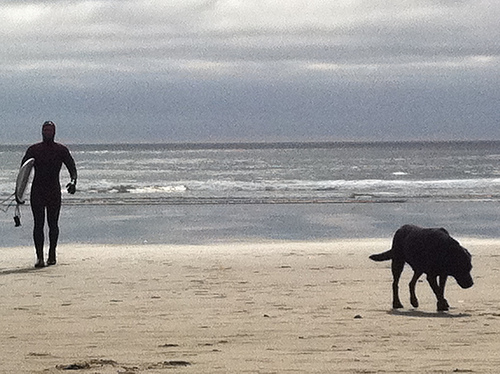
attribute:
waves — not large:
[3, 143, 494, 204]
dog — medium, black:
[369, 226, 481, 316]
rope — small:
[0, 191, 22, 228]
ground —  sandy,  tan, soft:
[379, 172, 402, 194]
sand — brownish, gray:
[161, 255, 326, 317]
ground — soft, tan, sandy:
[73, 248, 369, 369]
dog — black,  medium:
[368, 222, 474, 316]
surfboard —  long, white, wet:
[14, 156, 35, 205]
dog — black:
[374, 220, 473, 324]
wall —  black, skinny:
[348, 96, 395, 155]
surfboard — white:
[13, 162, 37, 202]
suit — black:
[14, 106, 91, 273]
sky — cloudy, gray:
[0, 0, 498, 140]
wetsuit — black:
[12, 142, 88, 250]